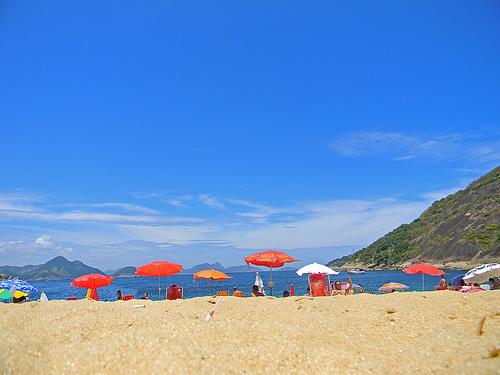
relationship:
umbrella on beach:
[131, 263, 177, 301] [5, 288, 497, 374]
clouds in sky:
[3, 194, 361, 247] [3, 7, 500, 261]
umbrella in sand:
[131, 263, 177, 301] [5, 288, 497, 374]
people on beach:
[5, 271, 488, 293] [5, 288, 497, 374]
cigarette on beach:
[202, 299, 230, 321] [5, 288, 497, 374]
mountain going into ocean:
[320, 161, 499, 273] [5, 271, 488, 293]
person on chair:
[171, 284, 181, 298] [163, 281, 185, 300]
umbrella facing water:
[196, 270, 231, 296] [5, 271, 488, 293]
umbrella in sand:
[196, 270, 231, 296] [5, 288, 497, 374]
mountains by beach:
[4, 257, 344, 273] [5, 288, 497, 374]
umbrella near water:
[376, 279, 411, 295] [5, 271, 488, 293]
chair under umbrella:
[163, 281, 185, 300] [376, 279, 411, 295]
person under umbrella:
[171, 284, 181, 298] [239, 249, 295, 300]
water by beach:
[1, 269, 495, 307] [5, 288, 497, 374]